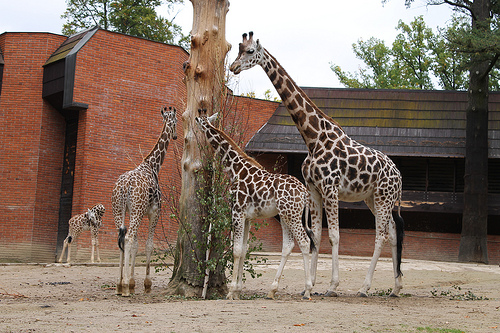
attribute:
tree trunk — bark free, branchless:
[162, 1, 234, 296]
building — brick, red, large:
[3, 29, 279, 266]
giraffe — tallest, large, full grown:
[227, 32, 415, 300]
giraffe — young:
[199, 108, 321, 302]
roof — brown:
[253, 83, 500, 158]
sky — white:
[1, 0, 498, 103]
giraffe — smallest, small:
[62, 204, 107, 265]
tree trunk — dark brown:
[440, 1, 496, 265]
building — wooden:
[260, 74, 500, 227]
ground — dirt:
[2, 241, 494, 332]